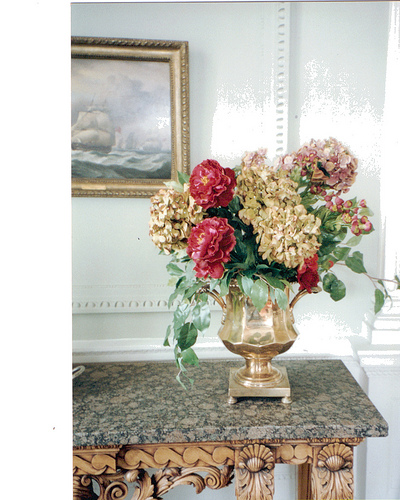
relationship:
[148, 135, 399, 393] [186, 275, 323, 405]
flowers in vase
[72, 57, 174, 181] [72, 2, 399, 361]
picture on wall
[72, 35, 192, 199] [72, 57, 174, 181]
frame on picture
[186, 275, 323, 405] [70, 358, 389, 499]
vase on table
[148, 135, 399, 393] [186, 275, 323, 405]
flowers over vase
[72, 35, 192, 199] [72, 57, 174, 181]
frame of picture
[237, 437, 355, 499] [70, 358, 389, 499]
legs of table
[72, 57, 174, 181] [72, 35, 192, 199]
picture in frame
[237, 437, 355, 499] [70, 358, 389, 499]
legs on table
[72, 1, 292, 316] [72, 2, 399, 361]
moulding on wall